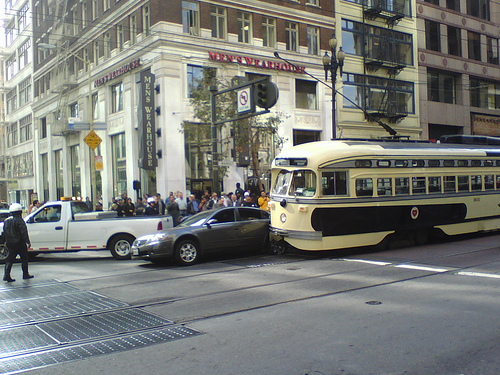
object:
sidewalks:
[210, 344, 500, 375]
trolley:
[269, 140, 500, 255]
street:
[0, 235, 500, 375]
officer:
[1, 203, 34, 285]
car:
[129, 206, 287, 267]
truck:
[0, 197, 173, 264]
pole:
[209, 76, 278, 196]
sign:
[237, 88, 251, 113]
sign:
[136, 71, 156, 170]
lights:
[257, 83, 267, 105]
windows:
[355, 174, 495, 196]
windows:
[272, 169, 317, 198]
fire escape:
[50, 2, 79, 136]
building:
[0, 0, 499, 212]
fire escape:
[360, 2, 410, 121]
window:
[295, 78, 319, 111]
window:
[343, 72, 415, 115]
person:
[166, 195, 180, 227]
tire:
[109, 234, 135, 260]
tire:
[0, 241, 11, 264]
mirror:
[209, 219, 218, 224]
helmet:
[9, 202, 23, 212]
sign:
[83, 130, 103, 151]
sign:
[208, 51, 305, 73]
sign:
[94, 59, 139, 89]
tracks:
[0, 245, 499, 361]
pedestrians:
[27, 186, 272, 228]